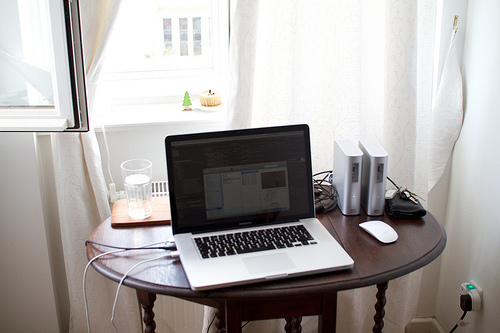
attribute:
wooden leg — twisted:
[218, 310, 245, 330]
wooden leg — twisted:
[82, 184, 459, 328]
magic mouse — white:
[357, 215, 399, 245]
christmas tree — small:
[178, 91, 195, 113]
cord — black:
[81, 241, 179, 331]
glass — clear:
[101, 146, 213, 237]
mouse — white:
[358, 215, 399, 245]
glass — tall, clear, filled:
[118, 155, 157, 222]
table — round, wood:
[66, 158, 463, 331]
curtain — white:
[42, 2, 156, 330]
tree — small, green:
[178, 91, 199, 108]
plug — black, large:
[459, 293, 474, 313]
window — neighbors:
[70, 13, 223, 114]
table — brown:
[351, 250, 428, 280]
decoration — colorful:
[201, 87, 222, 104]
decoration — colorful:
[180, 90, 190, 112]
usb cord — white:
[121, 249, 178, 271]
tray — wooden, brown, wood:
[109, 191, 174, 228]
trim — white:
[413, 313, 453, 330]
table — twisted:
[95, 217, 445, 331]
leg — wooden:
[373, 278, 390, 330]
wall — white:
[433, 15, 494, 257]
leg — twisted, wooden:
[282, 295, 305, 332]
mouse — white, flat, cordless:
[357, 217, 404, 252]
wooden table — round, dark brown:
[84, 186, 446, 331]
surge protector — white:
[460, 276, 486, 316]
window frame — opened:
[0, 2, 90, 132]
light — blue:
[464, 282, 480, 294]